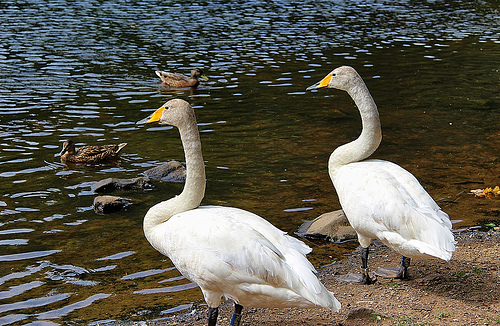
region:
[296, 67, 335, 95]
black and yellow duck bill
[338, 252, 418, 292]
black webbed duck feet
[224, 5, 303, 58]
small ripples on surface of water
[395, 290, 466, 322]
ground covered in brown dirt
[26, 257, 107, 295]
small black rock in water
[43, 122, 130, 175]
brown duck floating on water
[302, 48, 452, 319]
large white duck standing on shore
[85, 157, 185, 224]
group of rocks in water by duck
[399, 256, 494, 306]
shadow of duck on ground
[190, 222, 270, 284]
white feathers on wing of duck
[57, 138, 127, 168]
A female mallard duck.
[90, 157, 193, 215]
Rocks in the water.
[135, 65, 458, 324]
Two white geese.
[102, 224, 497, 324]
A bit of sandy shore.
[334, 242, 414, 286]
Two black goose feet.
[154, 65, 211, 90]
A duck floating on the water surface.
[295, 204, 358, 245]
A rock near the water's edge.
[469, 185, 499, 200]
Plant material floating on the surface of the water.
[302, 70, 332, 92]
The orange and black beak of a goose.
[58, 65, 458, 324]
Four water fowl.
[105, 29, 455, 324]
these are two geese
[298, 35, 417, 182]
its neck is curved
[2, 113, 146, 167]
this is a duck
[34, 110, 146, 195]
a duck wading in the water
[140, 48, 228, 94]
a duck is floating on the water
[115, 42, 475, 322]
the geese are on the shore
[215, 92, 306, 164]
the water looks brown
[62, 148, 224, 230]
large stones sticking up out of the water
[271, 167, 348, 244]
this is part of a large rock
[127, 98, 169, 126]
the beak is orange and black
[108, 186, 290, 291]
this is a bird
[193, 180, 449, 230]
these are two birds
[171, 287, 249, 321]
these are two legs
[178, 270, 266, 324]
the legs are black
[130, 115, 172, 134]
this is a beak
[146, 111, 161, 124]
the beak is yellow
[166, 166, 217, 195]
this is a neck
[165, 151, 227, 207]
the neck is long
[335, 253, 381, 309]
this is webbed feet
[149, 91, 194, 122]
this is an eye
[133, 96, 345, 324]
a bird with a long neck is white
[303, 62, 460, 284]
a bird with a long neck is white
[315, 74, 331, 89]
yellow part of a birds beak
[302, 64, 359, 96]
head of a bird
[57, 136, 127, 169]
brown duck in water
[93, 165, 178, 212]
a rock is in water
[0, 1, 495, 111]
light reflecting on water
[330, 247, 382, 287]
foot of a bird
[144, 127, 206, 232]
neck of a bird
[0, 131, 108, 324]
light is reflecting off of water